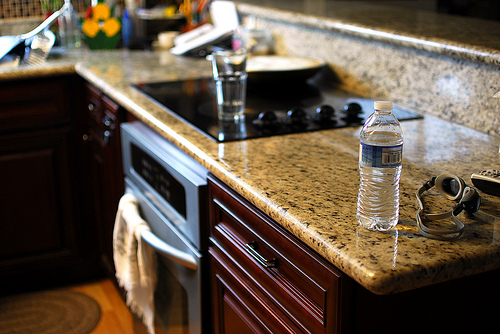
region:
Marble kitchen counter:
[1, 47, 498, 293]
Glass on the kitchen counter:
[210, 49, 247, 121]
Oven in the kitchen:
[116, 120, 208, 332]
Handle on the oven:
[118, 192, 196, 270]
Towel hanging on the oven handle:
[110, 192, 156, 333]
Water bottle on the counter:
[356, 99, 403, 231]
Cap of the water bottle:
[373, 99, 393, 112]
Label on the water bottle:
[357, 141, 403, 170]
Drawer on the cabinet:
[203, 174, 338, 332]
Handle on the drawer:
[242, 238, 279, 270]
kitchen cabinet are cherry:
[0, 65, 499, 332]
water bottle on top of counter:
[353, 96, 400, 231]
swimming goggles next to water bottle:
[414, 171, 484, 243]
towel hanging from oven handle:
[109, 190, 160, 332]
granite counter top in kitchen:
[1, 3, 496, 298]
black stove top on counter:
[127, 74, 434, 140]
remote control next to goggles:
[469, 164, 499, 200]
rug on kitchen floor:
[0, 278, 103, 333]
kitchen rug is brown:
[0, 286, 103, 332]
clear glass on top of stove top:
[209, 48, 251, 120]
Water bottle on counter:
[356, 88, 406, 233]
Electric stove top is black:
[137, 43, 407, 133]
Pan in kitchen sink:
[2, 8, 68, 71]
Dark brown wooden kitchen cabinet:
[211, 182, 337, 329]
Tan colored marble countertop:
[256, 133, 478, 270]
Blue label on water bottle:
[355, 127, 409, 177]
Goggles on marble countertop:
[414, 157, 482, 242]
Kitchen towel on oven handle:
[107, 187, 160, 325]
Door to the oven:
[109, 182, 219, 319]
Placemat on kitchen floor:
[2, 268, 103, 331]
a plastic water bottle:
[359, 93, 405, 230]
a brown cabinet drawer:
[200, 178, 343, 329]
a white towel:
[106, 187, 169, 332]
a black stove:
[125, 70, 425, 144]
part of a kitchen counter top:
[215, 117, 496, 289]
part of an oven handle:
[140, 227, 197, 270]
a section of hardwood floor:
[83, 277, 157, 331]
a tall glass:
[210, 50, 255, 121]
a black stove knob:
[310, 102, 341, 129]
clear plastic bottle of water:
[347, 97, 421, 236]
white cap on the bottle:
[370, 97, 395, 112]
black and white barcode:
[379, 150, 404, 164]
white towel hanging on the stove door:
[93, 178, 199, 332]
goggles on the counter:
[413, 162, 476, 242]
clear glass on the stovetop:
[207, 40, 257, 123]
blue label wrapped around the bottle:
[353, 137, 407, 171]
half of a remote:
[464, 162, 499, 190]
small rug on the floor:
[1, 280, 109, 332]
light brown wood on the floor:
[56, 252, 133, 330]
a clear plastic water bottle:
[356, 99, 403, 227]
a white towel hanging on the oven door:
[111, 193, 158, 331]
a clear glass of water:
[210, 47, 250, 121]